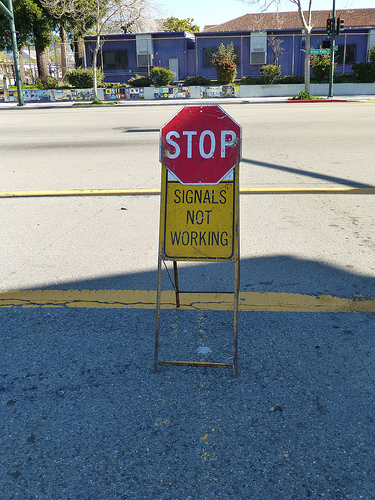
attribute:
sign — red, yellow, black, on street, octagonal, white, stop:
[134, 114, 265, 360]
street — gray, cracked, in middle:
[261, 159, 331, 271]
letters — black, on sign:
[170, 232, 238, 249]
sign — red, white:
[167, 89, 229, 171]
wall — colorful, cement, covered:
[98, 88, 246, 102]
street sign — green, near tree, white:
[304, 43, 347, 57]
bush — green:
[206, 43, 240, 82]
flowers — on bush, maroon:
[219, 59, 235, 70]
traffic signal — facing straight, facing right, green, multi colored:
[325, 22, 336, 40]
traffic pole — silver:
[329, 55, 341, 99]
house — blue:
[87, 30, 374, 87]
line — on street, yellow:
[10, 168, 124, 215]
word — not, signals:
[171, 207, 229, 228]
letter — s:
[163, 126, 193, 172]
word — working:
[167, 224, 237, 253]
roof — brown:
[243, 14, 303, 31]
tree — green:
[4, 3, 62, 87]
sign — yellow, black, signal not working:
[106, 177, 270, 261]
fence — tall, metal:
[110, 37, 169, 56]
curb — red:
[289, 96, 353, 106]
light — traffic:
[323, 9, 346, 45]